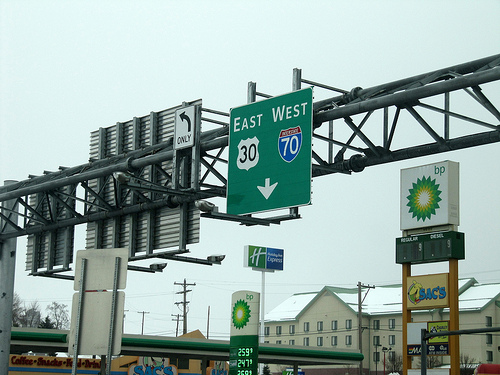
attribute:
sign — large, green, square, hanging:
[226, 86, 314, 217]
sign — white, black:
[172, 104, 195, 149]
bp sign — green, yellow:
[228, 289, 260, 374]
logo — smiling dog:
[407, 281, 445, 304]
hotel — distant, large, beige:
[259, 276, 498, 375]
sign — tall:
[243, 244, 284, 273]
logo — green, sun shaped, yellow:
[230, 299, 251, 330]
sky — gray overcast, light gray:
[1, 1, 498, 342]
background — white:
[230, 290, 259, 336]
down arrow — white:
[254, 177, 277, 202]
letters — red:
[10, 353, 103, 370]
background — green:
[228, 335, 259, 374]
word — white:
[232, 114, 264, 133]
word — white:
[270, 101, 308, 122]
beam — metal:
[0, 52, 497, 242]